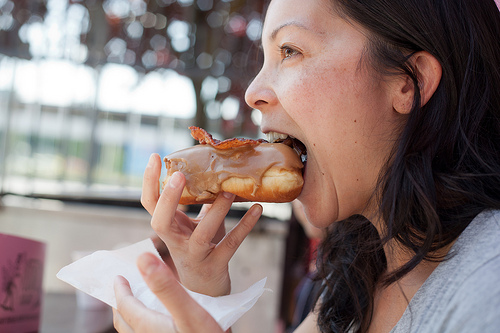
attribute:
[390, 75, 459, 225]
hair — black 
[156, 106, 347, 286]
donut — brown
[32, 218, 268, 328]
napkin — white 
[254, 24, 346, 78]
eye — brown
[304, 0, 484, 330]
hair — brown, long, black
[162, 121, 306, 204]
donut — designer, iced, brown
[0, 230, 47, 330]
sign — purple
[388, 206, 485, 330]
shirt — gray